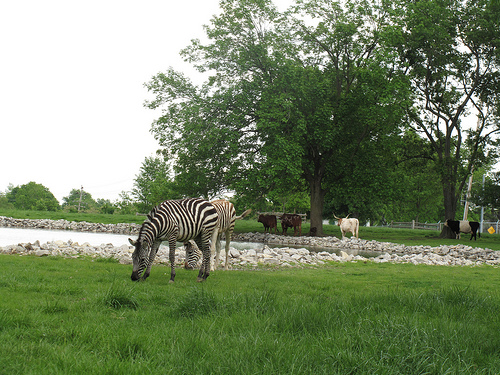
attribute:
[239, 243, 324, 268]
rocks — white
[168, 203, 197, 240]
stripes — black 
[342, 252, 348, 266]
rocks — white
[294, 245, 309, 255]
rocks — white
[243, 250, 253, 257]
rocks — white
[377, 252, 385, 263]
rocks — white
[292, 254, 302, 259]
rocks — white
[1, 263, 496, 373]
grass — green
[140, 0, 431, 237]
tree — brown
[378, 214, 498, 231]
fence — wooden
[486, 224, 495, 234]
sign — yellow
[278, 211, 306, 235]
cow — brown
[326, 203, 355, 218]
horns — long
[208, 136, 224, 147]
leaf — green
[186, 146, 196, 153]
leaf — green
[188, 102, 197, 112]
leaf — green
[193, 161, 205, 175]
leaf — green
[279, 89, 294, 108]
leaf — green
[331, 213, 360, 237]
cow — black, white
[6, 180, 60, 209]
trees — distant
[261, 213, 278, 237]
cow — brown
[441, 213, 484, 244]
cow — black, white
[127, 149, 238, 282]
zebra — black, white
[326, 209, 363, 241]
cattle — white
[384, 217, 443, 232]
fence — distant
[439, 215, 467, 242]
cow — black, white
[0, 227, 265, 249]
water — white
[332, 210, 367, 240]
cow — tan, white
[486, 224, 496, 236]
sign — yellow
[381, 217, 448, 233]
fence — wooden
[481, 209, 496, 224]
sign — yellow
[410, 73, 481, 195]
branches — tree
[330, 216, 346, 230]
patch — brown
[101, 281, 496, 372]
grass — tall, green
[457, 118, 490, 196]
branch — tree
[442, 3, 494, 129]
branch — tree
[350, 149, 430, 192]
branch — tree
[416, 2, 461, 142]
branch — tree